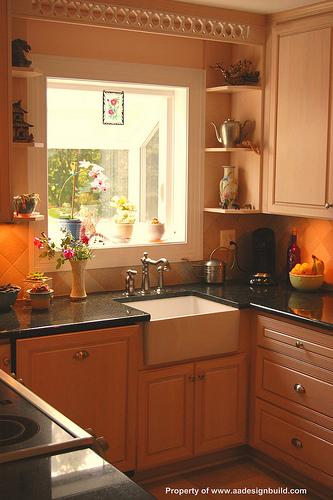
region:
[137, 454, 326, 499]
The floor is made of wood.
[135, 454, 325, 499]
The floor is brown.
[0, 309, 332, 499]
The cabinets are made of wood.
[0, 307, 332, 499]
The cabinets are brown.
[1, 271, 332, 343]
The countertop is black.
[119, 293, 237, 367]
The sink is white.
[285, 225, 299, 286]
A bottle.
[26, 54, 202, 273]
A window is in the wall.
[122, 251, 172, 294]
The faucet is gray.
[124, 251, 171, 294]
The faucet is made of metal.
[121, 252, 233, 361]
Kitchen sink with silve faucet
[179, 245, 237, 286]
A silver watering can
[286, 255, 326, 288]
A bowl of fruit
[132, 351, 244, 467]
Kitchen cabinets with knobs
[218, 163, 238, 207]
A decorative vase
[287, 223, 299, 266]
The top of a wine bottle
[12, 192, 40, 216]
A potted plant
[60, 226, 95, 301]
A vase of flowers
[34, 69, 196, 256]
A white trimmed window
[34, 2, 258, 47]
White decorative trimming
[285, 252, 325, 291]
bowl of oranges and bananas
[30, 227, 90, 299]
vase of pink flowers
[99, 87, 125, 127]
stained-glass flower window decoration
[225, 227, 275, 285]
coffee maker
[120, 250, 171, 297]
chrome kitchen sink faucet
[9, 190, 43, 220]
cactus in blue bowl on shelf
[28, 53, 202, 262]
window over kitchen sink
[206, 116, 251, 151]
silver teapot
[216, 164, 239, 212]
white vase with blue and pink accents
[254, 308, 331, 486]
set of three kitchen drawers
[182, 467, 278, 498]
a white and grey tile floor.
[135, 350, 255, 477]
brown cabinet doors.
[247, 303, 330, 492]
brown draws with gold knobs.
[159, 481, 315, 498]
a property of www.aadesignbuild.com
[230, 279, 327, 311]
a black counter top.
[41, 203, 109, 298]
a light brown vase with flowers.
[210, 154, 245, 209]
a colorful vase.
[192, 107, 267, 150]
a grey metal tea pot.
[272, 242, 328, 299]
a light green fruit bowl.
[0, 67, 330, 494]
a picture of a beautiful kitchen.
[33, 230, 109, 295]
pink flowers in a white vase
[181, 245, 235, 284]
a silver kettle on a counter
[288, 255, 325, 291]
a bowl of fruits on a counter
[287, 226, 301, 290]
a bottle of wine on a counter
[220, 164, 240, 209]
a vase on a shelf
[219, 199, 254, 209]
three figurines on a shelf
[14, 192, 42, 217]
a dying plant on a shelf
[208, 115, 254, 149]
a silver kettle on a shelf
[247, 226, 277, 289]
a black and silvery coffee machine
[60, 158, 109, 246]
an orchid plant in a pot on the window sill